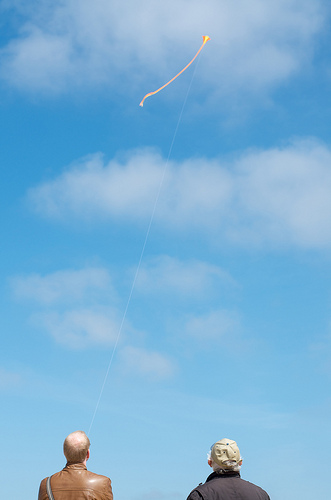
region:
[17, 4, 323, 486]
Photo taken during the day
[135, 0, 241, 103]
Kite up in the air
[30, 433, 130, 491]
Man flying a kite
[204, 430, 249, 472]
Hat on the man's head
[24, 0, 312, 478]
the sky is blue with clouds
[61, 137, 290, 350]
Clouds in the sky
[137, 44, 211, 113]
Tail of the kite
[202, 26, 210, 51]
Orange and yellow kite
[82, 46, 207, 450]
Long kite string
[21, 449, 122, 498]
Brown coat on the man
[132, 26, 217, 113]
kite flying in the air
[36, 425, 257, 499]
two men watching the kite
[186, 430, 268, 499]
man wearing black coat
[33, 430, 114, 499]
man wearing brown coat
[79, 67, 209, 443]
white string connected to the kite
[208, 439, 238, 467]
hat of man in black coat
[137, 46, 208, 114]
long tail of the kite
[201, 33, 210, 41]
orange and yellow kite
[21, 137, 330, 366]
wispy clouds in the blue sky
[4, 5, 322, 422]
blue sky kite is flying in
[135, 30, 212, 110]
a kite flies high in the sky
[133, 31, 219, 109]
the kite is orange and yellow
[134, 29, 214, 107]
the kite has a very long tail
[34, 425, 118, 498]
this gentleman is flying a kite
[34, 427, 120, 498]
this gentleman is wearing a leather jacket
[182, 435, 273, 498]
this gentleman is watching the flying kite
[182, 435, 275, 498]
this gentleman is wearing a black jacket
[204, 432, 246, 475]
this gentleman is wearing a hat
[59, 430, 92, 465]
this gentleman is balding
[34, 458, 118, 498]
this gentleman's jacket is brown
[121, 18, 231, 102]
a kite in the sky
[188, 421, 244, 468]
a hat on the head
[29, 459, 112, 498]
a brown leather jacket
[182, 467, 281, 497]
a black jacket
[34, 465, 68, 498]
a gray strap over shoulder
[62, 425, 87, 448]
a bald spot on head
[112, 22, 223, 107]
an orange and yellow kite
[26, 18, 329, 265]
white misty clouds in the sky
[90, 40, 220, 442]
white string from the kite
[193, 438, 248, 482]
white hair under hat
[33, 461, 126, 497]
Man wearing a jacket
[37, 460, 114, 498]
Man wearing a brown jacket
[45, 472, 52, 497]
Strap over man's shoulder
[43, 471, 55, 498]
Gray and white strap over man's shoulder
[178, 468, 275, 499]
Man is wearing a jacket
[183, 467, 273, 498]
Man is wearing a black jacket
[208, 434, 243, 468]
Man is wearing a hat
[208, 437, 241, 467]
Man is wearing a cream colored hat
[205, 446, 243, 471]
Man has hair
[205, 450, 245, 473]
Man has gray hair